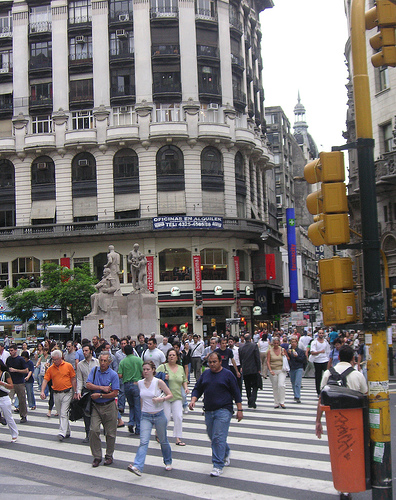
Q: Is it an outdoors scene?
A: Yes, it is outdoors.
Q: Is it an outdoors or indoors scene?
A: It is outdoors.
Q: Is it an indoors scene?
A: No, it is outdoors.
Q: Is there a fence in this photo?
A: No, there are no fences.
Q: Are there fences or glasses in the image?
A: No, there are no fences or glasses.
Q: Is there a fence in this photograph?
A: No, there are no fences.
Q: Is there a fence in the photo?
A: No, there are no fences.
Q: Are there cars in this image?
A: No, there are no cars.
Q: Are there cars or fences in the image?
A: No, there are no cars or fences.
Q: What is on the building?
A: The sign is on the building.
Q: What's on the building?
A: The sign is on the building.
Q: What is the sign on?
A: The sign is on the building.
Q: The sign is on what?
A: The sign is on the building.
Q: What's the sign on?
A: The sign is on the building.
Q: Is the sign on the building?
A: Yes, the sign is on the building.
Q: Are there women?
A: Yes, there is a woman.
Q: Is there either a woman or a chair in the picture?
A: Yes, there is a woman.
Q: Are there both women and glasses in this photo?
A: No, there is a woman but no glasses.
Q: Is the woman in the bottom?
A: Yes, the woman is in the bottom of the image.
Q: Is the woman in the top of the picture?
A: No, the woman is in the bottom of the image.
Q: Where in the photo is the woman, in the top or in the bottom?
A: The woman is in the bottom of the image.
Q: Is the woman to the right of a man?
A: No, the woman is to the left of a man.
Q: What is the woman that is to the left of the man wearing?
A: The woman is wearing a shirt.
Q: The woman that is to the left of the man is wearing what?
A: The woman is wearing a shirt.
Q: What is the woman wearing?
A: The woman is wearing a shirt.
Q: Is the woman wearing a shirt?
A: Yes, the woman is wearing a shirt.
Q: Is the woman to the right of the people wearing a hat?
A: No, the woman is wearing a shirt.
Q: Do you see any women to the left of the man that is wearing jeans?
A: Yes, there is a woman to the left of the man.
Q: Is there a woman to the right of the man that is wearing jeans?
A: No, the woman is to the left of the man.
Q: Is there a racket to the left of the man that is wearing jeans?
A: No, there is a woman to the left of the man.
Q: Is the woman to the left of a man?
A: Yes, the woman is to the left of a man.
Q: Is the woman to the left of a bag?
A: No, the woman is to the left of a man.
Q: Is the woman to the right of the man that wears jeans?
A: No, the woman is to the left of the man.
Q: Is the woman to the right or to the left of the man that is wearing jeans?
A: The woman is to the left of the man.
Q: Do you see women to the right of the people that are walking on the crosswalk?
A: Yes, there is a woman to the right of the people.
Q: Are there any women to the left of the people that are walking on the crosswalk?
A: No, the woman is to the right of the people.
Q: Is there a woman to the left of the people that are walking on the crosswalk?
A: No, the woman is to the right of the people.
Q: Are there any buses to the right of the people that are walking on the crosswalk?
A: No, there is a woman to the right of the people.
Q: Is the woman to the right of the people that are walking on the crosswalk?
A: Yes, the woman is to the right of the people.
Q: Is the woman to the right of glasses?
A: No, the woman is to the right of the people.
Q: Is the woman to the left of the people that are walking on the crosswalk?
A: No, the woman is to the right of the people.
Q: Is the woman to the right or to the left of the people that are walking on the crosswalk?
A: The woman is to the right of the people.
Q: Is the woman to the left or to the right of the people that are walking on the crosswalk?
A: The woman is to the right of the people.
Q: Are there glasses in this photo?
A: No, there are no glasses.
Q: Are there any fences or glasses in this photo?
A: No, there are no glasses or fences.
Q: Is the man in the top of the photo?
A: No, the man is in the bottom of the image.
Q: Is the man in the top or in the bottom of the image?
A: The man is in the bottom of the image.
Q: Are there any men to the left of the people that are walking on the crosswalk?
A: Yes, there is a man to the left of the people.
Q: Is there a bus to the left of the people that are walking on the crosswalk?
A: No, there is a man to the left of the people.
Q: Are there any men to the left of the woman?
A: Yes, there is a man to the left of the woman.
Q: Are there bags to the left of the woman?
A: No, there is a man to the left of the woman.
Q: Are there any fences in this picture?
A: No, there are no fences.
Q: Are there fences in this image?
A: No, there are no fences.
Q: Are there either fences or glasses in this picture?
A: No, there are no fences or glasses.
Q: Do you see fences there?
A: No, there are no fences.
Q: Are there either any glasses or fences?
A: No, there are no fences or glasses.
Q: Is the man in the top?
A: No, the man is in the bottom of the image.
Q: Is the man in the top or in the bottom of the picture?
A: The man is in the bottom of the image.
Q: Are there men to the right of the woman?
A: Yes, there is a man to the right of the woman.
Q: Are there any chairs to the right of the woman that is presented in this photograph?
A: No, there is a man to the right of the woman.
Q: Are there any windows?
A: Yes, there is a window.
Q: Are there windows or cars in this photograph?
A: Yes, there is a window.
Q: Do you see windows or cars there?
A: Yes, there is a window.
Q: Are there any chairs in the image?
A: No, there are no chairs.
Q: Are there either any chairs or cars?
A: No, there are no chairs or cars.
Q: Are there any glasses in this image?
A: No, there are no glasses.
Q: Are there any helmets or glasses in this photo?
A: No, there are no glasses or helmets.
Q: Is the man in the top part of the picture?
A: No, the man is in the bottom of the image.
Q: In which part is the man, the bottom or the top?
A: The man is in the bottom of the image.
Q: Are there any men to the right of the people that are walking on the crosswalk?
A: Yes, there is a man to the right of the people.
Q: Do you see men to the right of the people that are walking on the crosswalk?
A: Yes, there is a man to the right of the people.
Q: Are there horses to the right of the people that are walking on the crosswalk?
A: No, there is a man to the right of the people.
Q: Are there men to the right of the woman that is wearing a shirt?
A: Yes, there is a man to the right of the woman.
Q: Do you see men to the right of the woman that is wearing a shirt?
A: Yes, there is a man to the right of the woman.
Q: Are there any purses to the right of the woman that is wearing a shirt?
A: No, there is a man to the right of the woman.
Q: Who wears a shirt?
A: The man wears a shirt.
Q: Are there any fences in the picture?
A: No, there are no fences.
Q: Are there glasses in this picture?
A: No, there are no glasses.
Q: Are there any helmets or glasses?
A: No, there are no glasses or helmets.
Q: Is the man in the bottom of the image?
A: Yes, the man is in the bottom of the image.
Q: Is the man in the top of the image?
A: No, the man is in the bottom of the image.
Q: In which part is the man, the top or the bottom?
A: The man is in the bottom of the image.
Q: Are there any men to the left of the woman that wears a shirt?
A: Yes, there is a man to the left of the woman.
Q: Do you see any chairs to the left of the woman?
A: No, there is a man to the left of the woman.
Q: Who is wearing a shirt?
A: The man is wearing a shirt.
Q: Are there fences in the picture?
A: No, there are no fences.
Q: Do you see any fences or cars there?
A: No, there are no fences or cars.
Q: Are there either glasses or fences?
A: No, there are no fences or glasses.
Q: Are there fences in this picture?
A: No, there are no fences.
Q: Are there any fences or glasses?
A: No, there are no fences or glasses.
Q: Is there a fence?
A: No, there are no fences.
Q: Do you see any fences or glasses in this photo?
A: No, there are no fences or glasses.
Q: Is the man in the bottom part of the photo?
A: Yes, the man is in the bottom of the image.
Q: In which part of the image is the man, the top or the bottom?
A: The man is in the bottom of the image.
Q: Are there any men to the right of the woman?
A: Yes, there is a man to the right of the woman.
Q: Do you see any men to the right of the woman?
A: Yes, there is a man to the right of the woman.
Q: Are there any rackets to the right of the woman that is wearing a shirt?
A: No, there is a man to the right of the woman.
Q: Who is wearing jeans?
A: The man is wearing jeans.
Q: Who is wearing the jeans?
A: The man is wearing jeans.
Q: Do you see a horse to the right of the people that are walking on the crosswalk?
A: No, there is a man to the right of the people.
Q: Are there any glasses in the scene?
A: No, there are no glasses.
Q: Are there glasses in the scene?
A: No, there are no glasses.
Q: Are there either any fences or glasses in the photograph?
A: No, there are no glasses or fences.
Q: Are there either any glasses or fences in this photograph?
A: No, there are no fences or glasses.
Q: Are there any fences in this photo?
A: No, there are no fences.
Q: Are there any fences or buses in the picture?
A: No, there are no fences or buses.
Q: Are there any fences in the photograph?
A: No, there are no fences.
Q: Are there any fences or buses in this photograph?
A: No, there are no fences or buses.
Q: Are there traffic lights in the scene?
A: Yes, there is a traffic light.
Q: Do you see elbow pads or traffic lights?
A: Yes, there is a traffic light.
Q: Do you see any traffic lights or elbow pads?
A: Yes, there is a traffic light.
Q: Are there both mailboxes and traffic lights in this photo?
A: No, there is a traffic light but no mailboxes.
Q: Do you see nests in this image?
A: No, there are no nests.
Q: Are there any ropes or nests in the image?
A: No, there are no nests or ropes.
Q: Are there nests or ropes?
A: No, there are no nests or ropes.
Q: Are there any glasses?
A: No, there are no glasses.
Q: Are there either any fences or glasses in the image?
A: No, there are no glasses or fences.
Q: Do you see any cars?
A: No, there are no cars.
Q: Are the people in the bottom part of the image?
A: Yes, the people are in the bottom of the image.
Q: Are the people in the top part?
A: No, the people are in the bottom of the image.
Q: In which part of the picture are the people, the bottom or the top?
A: The people are in the bottom of the image.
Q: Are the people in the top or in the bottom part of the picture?
A: The people are in the bottom of the image.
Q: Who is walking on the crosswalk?
A: The people are walking on the crosswalk.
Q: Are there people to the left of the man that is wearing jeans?
A: Yes, there are people to the left of the man.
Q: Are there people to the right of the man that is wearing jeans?
A: No, the people are to the left of the man.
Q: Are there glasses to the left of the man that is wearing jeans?
A: No, there are people to the left of the man.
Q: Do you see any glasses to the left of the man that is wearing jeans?
A: No, there are people to the left of the man.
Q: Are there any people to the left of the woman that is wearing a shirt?
A: Yes, there are people to the left of the woman.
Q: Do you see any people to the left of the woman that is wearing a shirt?
A: Yes, there are people to the left of the woman.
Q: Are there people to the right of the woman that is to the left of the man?
A: No, the people are to the left of the woman.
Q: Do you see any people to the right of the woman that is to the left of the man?
A: No, the people are to the left of the woman.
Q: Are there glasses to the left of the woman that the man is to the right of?
A: No, there are people to the left of the woman.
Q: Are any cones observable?
A: No, there are no cones.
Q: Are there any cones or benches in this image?
A: No, there are no cones or benches.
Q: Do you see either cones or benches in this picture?
A: No, there are no cones or benches.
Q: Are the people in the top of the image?
A: No, the people are in the bottom of the image.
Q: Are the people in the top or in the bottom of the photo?
A: The people are in the bottom of the image.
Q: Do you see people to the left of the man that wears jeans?
A: Yes, there are people to the left of the man.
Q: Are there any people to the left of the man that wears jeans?
A: Yes, there are people to the left of the man.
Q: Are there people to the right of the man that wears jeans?
A: No, the people are to the left of the man.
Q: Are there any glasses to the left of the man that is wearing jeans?
A: No, there are people to the left of the man.